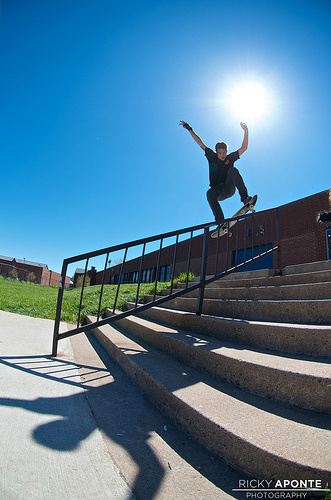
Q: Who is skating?
A: The guy.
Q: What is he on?
A: Skateboard.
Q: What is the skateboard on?
A: The rail.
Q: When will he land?
A: Soon.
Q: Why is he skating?
A: For fun.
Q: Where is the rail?
A: On the stairs.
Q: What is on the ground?
A: Shadow.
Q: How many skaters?
A: 1.